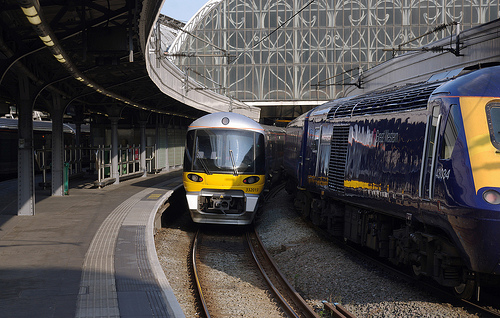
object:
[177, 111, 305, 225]
train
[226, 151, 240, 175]
wiper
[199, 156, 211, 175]
wiper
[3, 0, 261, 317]
station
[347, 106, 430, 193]
window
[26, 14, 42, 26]
lights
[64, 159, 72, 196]
can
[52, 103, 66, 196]
pole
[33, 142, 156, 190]
walkway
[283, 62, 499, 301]
trains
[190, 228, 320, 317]
railroad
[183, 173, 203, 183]
headlights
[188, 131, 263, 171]
windshield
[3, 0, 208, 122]
ceiling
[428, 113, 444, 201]
handles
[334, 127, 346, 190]
vents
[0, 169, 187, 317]
platform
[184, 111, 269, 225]
engine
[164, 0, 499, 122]
buliding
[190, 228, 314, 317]
pantographs